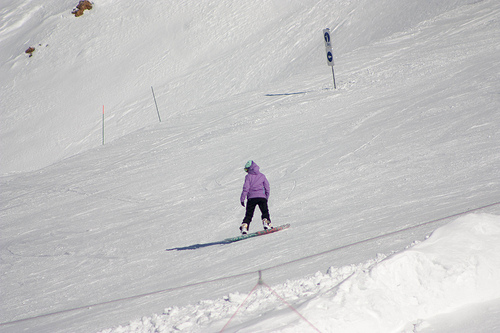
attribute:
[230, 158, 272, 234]
person — snowboarding, skiing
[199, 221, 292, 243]
snowboard — used, multi colored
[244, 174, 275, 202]
jacket — purple, fluffy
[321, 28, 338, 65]
sign — directions, white, black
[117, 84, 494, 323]
snow — white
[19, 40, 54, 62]
rocks — small, brown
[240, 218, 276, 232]
boots — black, white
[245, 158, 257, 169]
hat — green, blue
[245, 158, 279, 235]
girl — little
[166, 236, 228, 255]
shadow — snowboarder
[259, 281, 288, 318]
string — red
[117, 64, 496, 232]
hill — smth